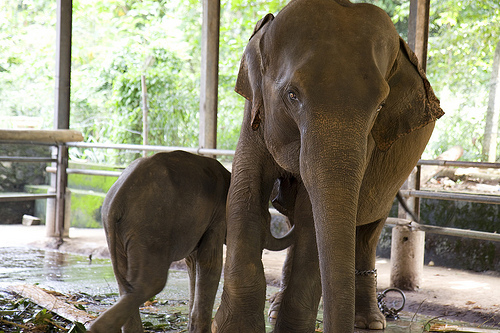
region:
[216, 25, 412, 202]
the elephant has eyes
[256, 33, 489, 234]
the elephant has eyes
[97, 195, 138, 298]
The tail of the smaller elephant.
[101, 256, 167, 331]
The back legs of the smaller elephant.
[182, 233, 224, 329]
The front legs of the elephant.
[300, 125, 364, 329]
The trunk of the larger elephant.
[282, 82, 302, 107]
The left eye of the larger elephant.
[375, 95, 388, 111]
The right eye of the larger elephant.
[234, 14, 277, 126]
The left ear of the larger elephant.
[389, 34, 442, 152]
The right ear of the larger elephant.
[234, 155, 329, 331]
The front legs of the larger elephant.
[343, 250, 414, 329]
The chain around the larger elephant's back leg.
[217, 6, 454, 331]
Large brown elephant facing the camera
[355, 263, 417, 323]
Chain around elephant's foot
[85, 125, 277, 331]
Younger baby elephant facing away from camera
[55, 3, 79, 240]
Tall wooden beam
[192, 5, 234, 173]
Tall wooden beam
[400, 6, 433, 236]
Tall wooden beam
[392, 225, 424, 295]
Cement block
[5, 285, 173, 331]
Plant leaves on the ground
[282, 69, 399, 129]
Pair of elephant eyes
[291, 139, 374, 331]
Long brown trunk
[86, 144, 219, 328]
a baby elephant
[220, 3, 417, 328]
a mama elephant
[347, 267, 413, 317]
a chain around the mama elephant's leg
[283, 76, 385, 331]
an elephant trunk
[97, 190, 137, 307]
an elephant tail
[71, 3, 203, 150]
a tree in the background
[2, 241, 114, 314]
water in the elephant cage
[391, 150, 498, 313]
bars in the elephant cage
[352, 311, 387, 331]
elephant toes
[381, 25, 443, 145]
this is an elephant ear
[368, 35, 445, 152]
large grey elephant ear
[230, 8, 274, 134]
large grey elephant ear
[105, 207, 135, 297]
tail of a baby elephant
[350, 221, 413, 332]
elephants leg chained to the ground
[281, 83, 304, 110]
eye on an elephant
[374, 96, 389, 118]
eye on an elephant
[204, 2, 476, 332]
the elephant is chained to the ground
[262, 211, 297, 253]
a baby elephant trunk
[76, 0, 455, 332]
mother elephant with her baby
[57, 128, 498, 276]
a metal tube gate